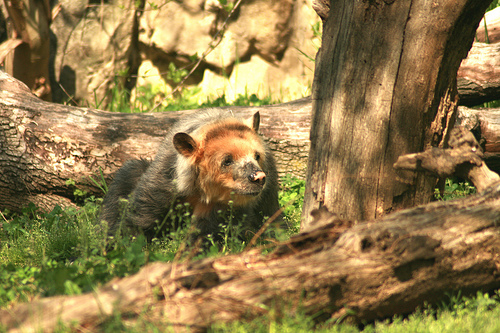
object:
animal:
[102, 108, 288, 245]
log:
[0, 67, 500, 215]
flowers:
[164, 202, 193, 225]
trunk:
[1, 39, 498, 219]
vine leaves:
[160, 62, 202, 98]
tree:
[324, 2, 466, 207]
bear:
[95, 108, 290, 255]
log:
[0, 187, 499, 331]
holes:
[357, 227, 400, 263]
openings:
[252, 222, 348, 269]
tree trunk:
[1, 145, 496, 330]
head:
[185, 130, 271, 213]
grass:
[0, 172, 498, 332]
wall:
[0, 0, 324, 112]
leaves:
[44, 207, 124, 259]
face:
[190, 129, 272, 202]